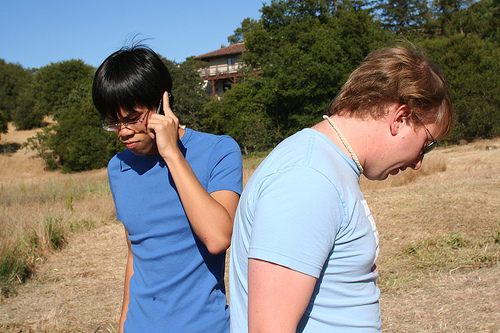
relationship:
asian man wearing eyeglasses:
[90, 32, 244, 331] [100, 108, 154, 133]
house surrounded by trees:
[183, 36, 300, 105] [247, 2, 342, 94]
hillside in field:
[360, 140, 499, 330] [4, 124, 484, 294]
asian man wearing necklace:
[90, 32, 244, 331] [319, 113, 365, 175]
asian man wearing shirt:
[90, 32, 244, 331] [87, 124, 265, 328]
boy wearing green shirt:
[223, 35, 458, 332] [225, 128, 384, 333]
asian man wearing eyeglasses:
[90, 32, 244, 331] [97, 103, 158, 137]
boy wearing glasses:
[223, 35, 458, 332] [405, 101, 443, 154]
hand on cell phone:
[146, 87, 178, 158] [154, 93, 174, 118]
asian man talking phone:
[90, 32, 244, 331] [151, 91, 176, 131]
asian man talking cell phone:
[90, 32, 244, 331] [154, 98, 165, 115]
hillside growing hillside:
[360, 140, 499, 330] [360, 140, 499, 330]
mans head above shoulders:
[85, 44, 179, 157] [106, 128, 238, 165]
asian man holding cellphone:
[90, 32, 244, 331] [148, 87, 179, 142]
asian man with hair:
[90, 32, 244, 331] [87, 40, 177, 109]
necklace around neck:
[319, 113, 371, 166] [288, 101, 403, 179]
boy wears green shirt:
[223, 35, 458, 332] [225, 115, 390, 331]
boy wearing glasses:
[223, 35, 458, 332] [404, 105, 439, 154]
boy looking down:
[208, 32, 471, 332] [356, 61, 446, 166]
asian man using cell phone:
[90, 32, 244, 331] [154, 93, 177, 118]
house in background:
[196, 36, 262, 105] [4, 4, 498, 153]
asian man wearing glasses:
[90, 32, 244, 331] [94, 107, 155, 132]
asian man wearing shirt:
[90, 32, 244, 331] [100, 115, 243, 331]